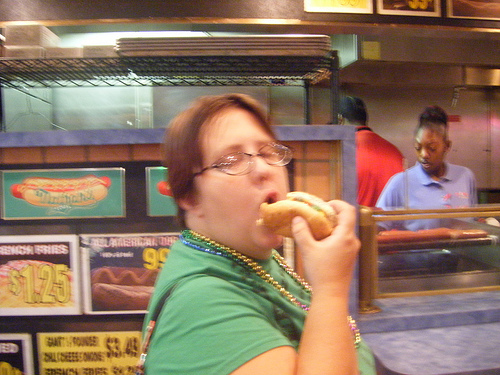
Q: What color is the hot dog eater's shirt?
A: Green.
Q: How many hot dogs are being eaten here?
A: One.